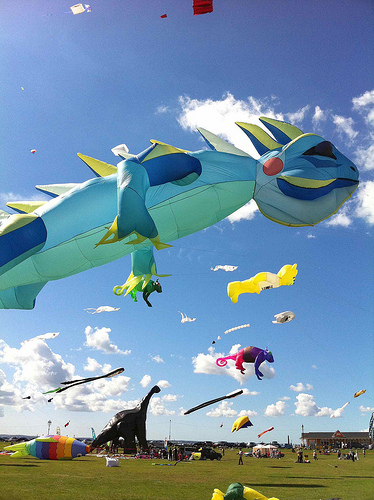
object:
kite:
[272, 310, 296, 324]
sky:
[9, 26, 366, 110]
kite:
[64, 2, 92, 16]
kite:
[330, 400, 351, 419]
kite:
[226, 262, 298, 304]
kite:
[216, 345, 274, 380]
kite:
[212, 323, 250, 344]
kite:
[257, 426, 274, 438]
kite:
[49, 367, 125, 403]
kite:
[210, 264, 239, 272]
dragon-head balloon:
[234, 116, 360, 228]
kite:
[184, 389, 244, 416]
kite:
[354, 389, 367, 398]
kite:
[231, 415, 254, 433]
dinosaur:
[0, 115, 360, 312]